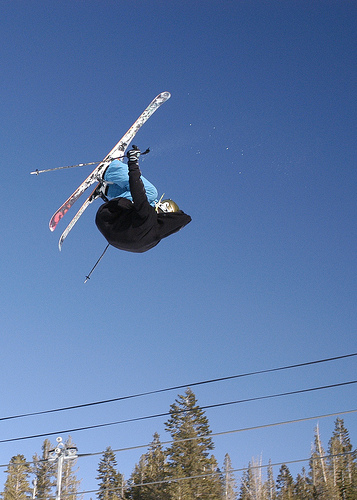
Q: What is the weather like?
A: Sunny and clear.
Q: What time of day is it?
A: Afternoon.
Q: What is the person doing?
A: Ski trick.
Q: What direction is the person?
A: Upside down.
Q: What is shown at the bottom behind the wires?
A: Trees.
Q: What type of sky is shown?
A: Clear blue.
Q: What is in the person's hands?
A: Ski poles.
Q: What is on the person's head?
A: Helmet.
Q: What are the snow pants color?
A: Blue.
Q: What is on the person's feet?
A: Skis.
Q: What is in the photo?
A: Person doing trick.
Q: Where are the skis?
A: Man feet.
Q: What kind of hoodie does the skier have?
A: Black.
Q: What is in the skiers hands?
A: Poles.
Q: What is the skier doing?
A: A trick in the air.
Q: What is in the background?
A: Trees.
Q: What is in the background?
A: Wires.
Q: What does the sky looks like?
A: Clear.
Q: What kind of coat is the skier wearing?
A: Black.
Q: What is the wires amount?
A: Four.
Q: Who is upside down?
A: A skier, wearing light, blue pants.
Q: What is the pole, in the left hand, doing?
A: Dangling, past the left ski, in mid-air.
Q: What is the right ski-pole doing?
A: Jutting out, behind the skier.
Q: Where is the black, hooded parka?
A: On the flipped over, mid air skier.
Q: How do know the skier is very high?
A: The electrical wires, criss-crossing the sky, are below the skier.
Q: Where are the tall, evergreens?
A: In a wooded area, just past the wire.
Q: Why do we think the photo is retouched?
A: There appears to be a helmet. stuffed inside the hood of the parka.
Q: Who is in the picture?
A: A young woman.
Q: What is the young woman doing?
A: Making a ski jump.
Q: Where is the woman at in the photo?
A: In mid air.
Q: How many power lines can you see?
A: 4.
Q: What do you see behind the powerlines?
A: Trees.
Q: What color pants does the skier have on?
A: Light blue.